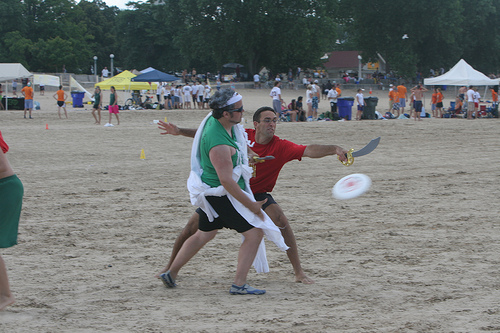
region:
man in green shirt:
[155, 82, 282, 300]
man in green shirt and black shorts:
[159, 81, 279, 301]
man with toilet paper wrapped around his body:
[149, 85, 275, 298]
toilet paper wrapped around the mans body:
[180, 106, 290, 274]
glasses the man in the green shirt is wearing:
[232, 104, 244, 116]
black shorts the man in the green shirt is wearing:
[180, 184, 262, 243]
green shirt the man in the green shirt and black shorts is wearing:
[188, 109, 253, 195]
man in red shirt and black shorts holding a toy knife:
[145, 98, 385, 286]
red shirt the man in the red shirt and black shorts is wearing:
[228, 123, 307, 196]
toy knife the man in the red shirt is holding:
[338, 134, 381, 162]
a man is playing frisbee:
[151, 76, 380, 297]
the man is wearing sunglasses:
[216, 100, 247, 119]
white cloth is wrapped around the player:
[156, 81, 287, 298]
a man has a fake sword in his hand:
[154, 104, 382, 174]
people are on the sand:
[14, 76, 494, 326]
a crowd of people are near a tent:
[133, 66, 215, 108]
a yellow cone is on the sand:
[136, 144, 150, 164]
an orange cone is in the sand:
[40, 118, 55, 135]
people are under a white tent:
[420, 57, 499, 120]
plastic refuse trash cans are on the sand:
[68, 90, 380, 120]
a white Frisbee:
[332, 168, 372, 199]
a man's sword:
[335, 133, 389, 165]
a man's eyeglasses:
[256, 115, 281, 126]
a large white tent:
[418, 53, 498, 89]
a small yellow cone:
[137, 146, 148, 157]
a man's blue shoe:
[225, 280, 267, 295]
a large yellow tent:
[93, 66, 154, 88]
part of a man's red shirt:
[241, 125, 309, 195]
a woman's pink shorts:
[105, 102, 117, 112]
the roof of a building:
[320, 47, 364, 67]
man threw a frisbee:
[244, 98, 381, 204]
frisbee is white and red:
[329, 160, 382, 210]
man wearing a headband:
[198, 75, 249, 118]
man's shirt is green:
[173, 107, 253, 197]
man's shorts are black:
[186, 183, 246, 235]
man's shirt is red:
[240, 126, 293, 194]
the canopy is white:
[413, 43, 496, 103]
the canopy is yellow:
[93, 58, 149, 100]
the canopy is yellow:
[133, 59, 179, 96]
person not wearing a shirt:
[405, 80, 431, 105]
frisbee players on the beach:
[10, 19, 469, 307]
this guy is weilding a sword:
[246, 88, 398, 285]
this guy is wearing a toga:
[185, 88, 262, 298]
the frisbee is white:
[308, 161, 386, 210]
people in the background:
[25, 59, 481, 128]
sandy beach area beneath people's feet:
[42, 132, 487, 317]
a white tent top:
[417, 54, 499, 89]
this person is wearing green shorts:
[1, 143, 46, 278]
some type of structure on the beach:
[3, 56, 35, 109]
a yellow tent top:
[101, 62, 153, 96]